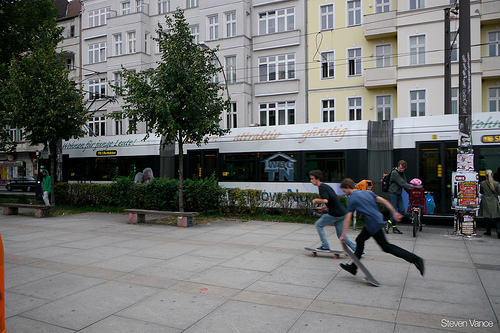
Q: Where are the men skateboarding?
A: Sidewalk.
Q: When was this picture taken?
A: Daytime.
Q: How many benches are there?
A: 2.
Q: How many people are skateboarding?
A: 2.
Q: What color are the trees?
A: Green.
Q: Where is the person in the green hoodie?
A: Near tree.